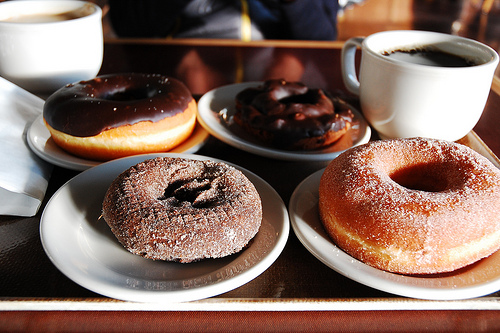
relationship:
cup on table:
[340, 26, 498, 140] [0, 40, 499, 332]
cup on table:
[2, 0, 105, 91] [0, 40, 499, 332]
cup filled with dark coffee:
[340, 26, 498, 140] [381, 45, 480, 66]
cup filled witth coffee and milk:
[2, 0, 105, 91] [4, 13, 88, 23]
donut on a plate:
[104, 156, 262, 260] [37, 152, 291, 305]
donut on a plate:
[318, 137, 499, 274] [290, 167, 499, 300]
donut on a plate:
[45, 72, 197, 158] [28, 110, 209, 170]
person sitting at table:
[110, 0, 339, 41] [0, 40, 499, 332]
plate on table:
[37, 152, 291, 305] [0, 40, 499, 332]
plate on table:
[290, 167, 499, 300] [0, 40, 499, 332]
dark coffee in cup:
[381, 45, 480, 66] [340, 26, 498, 140]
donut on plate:
[104, 156, 262, 260] [37, 152, 291, 305]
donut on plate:
[318, 137, 499, 274] [290, 167, 499, 300]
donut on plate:
[45, 72, 197, 158] [28, 110, 209, 170]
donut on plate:
[233, 79, 356, 148] [197, 83, 371, 161]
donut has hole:
[318, 137, 499, 274] [391, 161, 456, 194]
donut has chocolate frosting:
[45, 72, 197, 158] [42, 75, 191, 135]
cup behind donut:
[2, 0, 105, 91] [45, 72, 197, 158]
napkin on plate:
[1, 77, 52, 218] [37, 152, 291, 302]